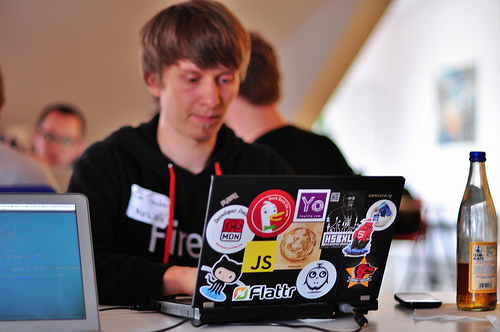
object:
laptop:
[151, 175, 408, 322]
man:
[60, 0, 300, 308]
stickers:
[296, 259, 338, 302]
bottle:
[453, 152, 499, 311]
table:
[407, 295, 500, 327]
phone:
[395, 291, 442, 308]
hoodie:
[68, 118, 298, 310]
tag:
[127, 186, 173, 227]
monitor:
[1, 190, 96, 332]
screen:
[195, 176, 402, 314]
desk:
[0, 306, 500, 332]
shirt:
[253, 123, 352, 183]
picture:
[426, 62, 481, 144]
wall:
[355, 10, 497, 137]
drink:
[454, 150, 499, 314]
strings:
[161, 167, 178, 266]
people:
[227, 29, 361, 177]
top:
[466, 151, 490, 164]